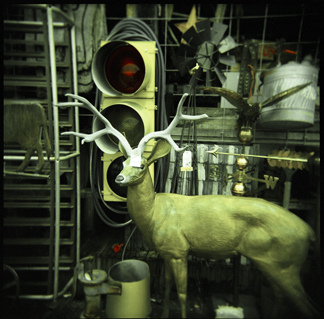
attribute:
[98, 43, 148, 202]
lights — shining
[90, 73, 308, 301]
deer — standing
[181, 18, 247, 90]
windmill — metal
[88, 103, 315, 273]
deer — standing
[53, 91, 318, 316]
deer — standing, fake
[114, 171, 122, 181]
nose — black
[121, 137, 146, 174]
tag — white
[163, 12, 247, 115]
windmill — metal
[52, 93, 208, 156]
antlers — white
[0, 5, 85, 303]
rack — metal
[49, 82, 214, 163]
antlers — white